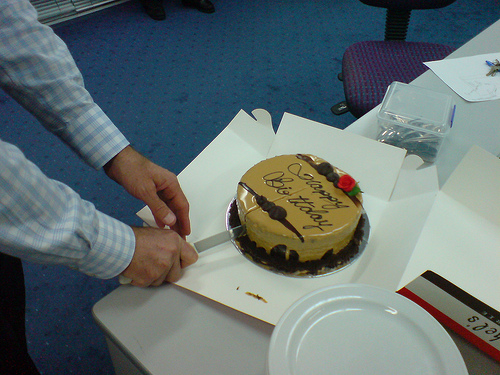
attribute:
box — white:
[142, 142, 427, 270]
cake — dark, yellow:
[231, 151, 364, 268]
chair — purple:
[340, 0, 463, 115]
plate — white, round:
[267, 283, 468, 372]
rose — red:
[336, 172, 355, 192]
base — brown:
[227, 200, 372, 275]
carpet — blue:
[1, 1, 498, 373]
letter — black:
[264, 170, 291, 192]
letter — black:
[268, 157, 343, 231]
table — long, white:
[85, 21, 496, 373]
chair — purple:
[329, 0, 474, 127]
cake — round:
[217, 151, 396, 295]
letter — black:
[318, 190, 338, 205]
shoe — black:
[143, 3, 168, 20]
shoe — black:
[181, 0, 221, 17]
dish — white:
[270, 285, 468, 374]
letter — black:
[265, 174, 294, 196]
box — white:
[108, 103, 498, 356]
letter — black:
[283, 160, 318, 180]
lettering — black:
[267, 160, 350, 218]